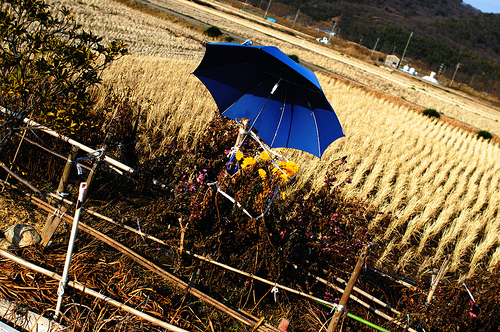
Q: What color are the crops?
A: Brown.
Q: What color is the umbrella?
A: Blue.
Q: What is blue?
A: The umbrella and the sky.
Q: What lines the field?
A: A row of trees.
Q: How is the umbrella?
A: Open.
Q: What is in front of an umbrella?
A: A broken fence.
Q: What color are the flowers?
A: Yellow.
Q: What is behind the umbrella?
A: A field.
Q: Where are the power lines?
A: In front of the trees.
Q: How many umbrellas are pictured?
A: One.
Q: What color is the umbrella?
A: Blue.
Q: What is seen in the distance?
A: A mountain.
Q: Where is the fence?
A: Around the umbrella.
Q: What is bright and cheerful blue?
A: The umbrella.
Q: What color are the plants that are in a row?
A: Yellow.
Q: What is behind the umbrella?
A: A wheat field.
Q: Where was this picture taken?
A: In the country.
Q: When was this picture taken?
A: During the day.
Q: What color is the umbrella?
A: Blue.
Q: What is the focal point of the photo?
A: The umbrella.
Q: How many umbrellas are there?
A: One.